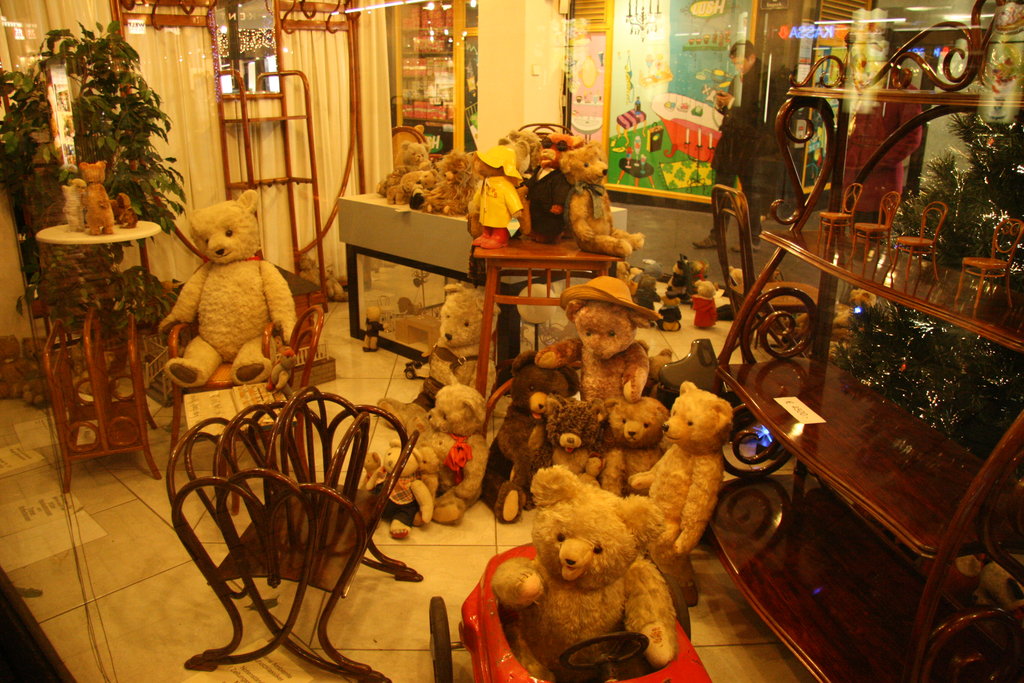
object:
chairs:
[819, 182, 1024, 322]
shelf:
[710, 0, 1022, 683]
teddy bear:
[536, 275, 665, 450]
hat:
[559, 276, 665, 321]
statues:
[61, 161, 137, 236]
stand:
[33, 220, 162, 494]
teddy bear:
[158, 189, 298, 388]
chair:
[169, 305, 327, 457]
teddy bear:
[429, 375, 492, 525]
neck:
[443, 434, 471, 485]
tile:
[50, 501, 170, 599]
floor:
[0, 301, 807, 683]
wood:
[717, 358, 1021, 558]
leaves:
[0, 20, 187, 338]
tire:
[427, 598, 451, 682]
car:
[429, 542, 716, 683]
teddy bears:
[468, 130, 644, 258]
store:
[0, 0, 1024, 683]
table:
[476, 240, 626, 400]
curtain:
[276, 1, 396, 282]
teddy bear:
[484, 377, 586, 448]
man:
[692, 40, 772, 252]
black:
[707, 58, 776, 245]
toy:
[490, 464, 676, 682]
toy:
[629, 382, 735, 608]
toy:
[603, 396, 671, 498]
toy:
[466, 145, 523, 250]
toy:
[559, 141, 646, 256]